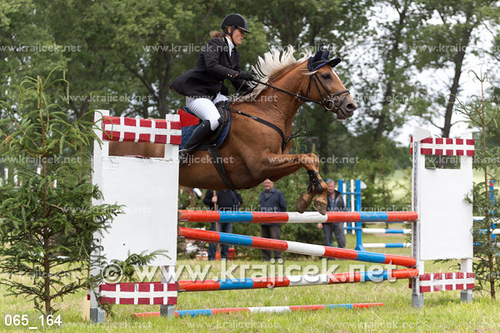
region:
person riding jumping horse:
[163, 12, 354, 194]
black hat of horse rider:
[215, 12, 248, 37]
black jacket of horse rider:
[168, 27, 246, 88]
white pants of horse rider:
[183, 94, 220, 124]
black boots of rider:
[182, 124, 212, 169]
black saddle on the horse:
[178, 105, 223, 143]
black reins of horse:
[228, 49, 351, 129]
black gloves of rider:
[240, 61, 252, 81]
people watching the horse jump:
[198, 164, 352, 244]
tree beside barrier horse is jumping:
[9, 59, 91, 310]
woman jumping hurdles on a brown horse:
[75, 8, 451, 318]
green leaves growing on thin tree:
[8, 65, 163, 315]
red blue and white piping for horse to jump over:
[158, 200, 428, 324]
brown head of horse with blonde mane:
[255, 37, 362, 134]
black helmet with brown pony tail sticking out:
[208, 9, 255, 52]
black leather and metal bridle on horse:
[276, 46, 370, 133]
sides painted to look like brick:
[396, 120, 483, 317]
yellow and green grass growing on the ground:
[403, 309, 458, 331]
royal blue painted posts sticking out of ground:
[338, 167, 370, 264]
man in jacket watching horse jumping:
[248, 172, 303, 262]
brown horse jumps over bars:
[144, 56, 356, 208]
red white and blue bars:
[184, 198, 416, 245]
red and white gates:
[405, 133, 465, 310]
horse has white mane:
[267, 49, 327, 84]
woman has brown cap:
[226, 11, 253, 36]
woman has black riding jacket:
[172, 40, 243, 87]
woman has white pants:
[191, 105, 238, 137]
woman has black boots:
[187, 115, 222, 164]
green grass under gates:
[221, 262, 366, 320]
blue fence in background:
[311, 173, 378, 249]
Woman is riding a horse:
[130, 13, 361, 198]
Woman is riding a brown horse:
[91, 10, 353, 220]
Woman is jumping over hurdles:
[85, 10, 360, 217]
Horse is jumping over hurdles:
[92, 45, 357, 218]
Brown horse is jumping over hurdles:
[87, 42, 359, 221]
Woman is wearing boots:
[163, 115, 228, 170]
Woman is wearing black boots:
[171, 115, 223, 160]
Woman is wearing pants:
[183, 90, 243, 131]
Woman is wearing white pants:
[184, 90, 232, 129]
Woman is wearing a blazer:
[168, 35, 245, 102]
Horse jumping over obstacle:
[184, 129, 333, 279]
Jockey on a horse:
[173, 48, 258, 139]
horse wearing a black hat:
[298, 41, 336, 81]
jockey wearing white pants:
[191, 90, 222, 129]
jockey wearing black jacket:
[187, 36, 232, 83]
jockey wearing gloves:
[235, 54, 260, 93]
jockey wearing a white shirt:
[218, 38, 233, 74]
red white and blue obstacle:
[140, 152, 492, 314]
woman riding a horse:
[228, 67, 318, 187]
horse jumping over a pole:
[218, 89, 387, 267]